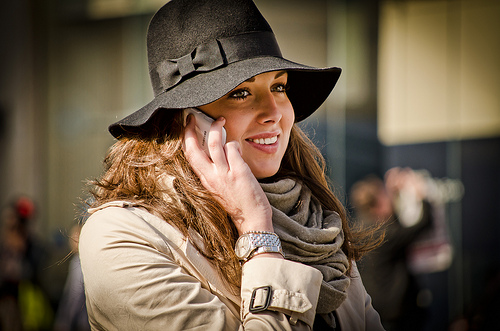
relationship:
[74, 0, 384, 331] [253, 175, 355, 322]
lady wearing scarf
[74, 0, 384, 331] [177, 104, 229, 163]
lady talking on phone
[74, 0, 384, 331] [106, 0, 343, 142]
lady wearing cap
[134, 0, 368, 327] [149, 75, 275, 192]
lady talking on phone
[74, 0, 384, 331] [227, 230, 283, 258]
lady wearing watch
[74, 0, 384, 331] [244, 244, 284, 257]
lady wearing watch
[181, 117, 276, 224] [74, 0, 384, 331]
hand belonging to lady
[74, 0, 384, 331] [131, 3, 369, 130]
lady wearing hat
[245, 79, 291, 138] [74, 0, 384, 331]
nose belonging to lady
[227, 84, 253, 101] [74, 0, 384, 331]
eye belonging to lady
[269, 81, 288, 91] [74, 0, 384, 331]
eye belonging to lady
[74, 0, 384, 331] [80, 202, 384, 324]
lady wearing coat